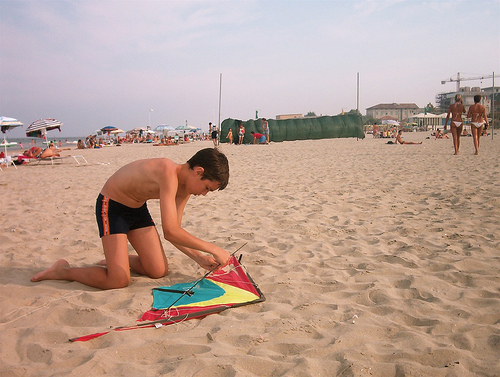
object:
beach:
[0, 145, 500, 377]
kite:
[68, 252, 267, 341]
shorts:
[95, 192, 156, 238]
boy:
[30, 147, 229, 290]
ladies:
[444, 94, 467, 156]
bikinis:
[471, 113, 483, 128]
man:
[394, 130, 423, 144]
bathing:
[393, 130, 423, 145]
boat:
[0, 139, 18, 146]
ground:
[84, 147, 499, 323]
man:
[250, 131, 268, 144]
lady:
[23, 146, 60, 159]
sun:
[81, 72, 155, 102]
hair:
[187, 147, 229, 191]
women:
[467, 94, 489, 155]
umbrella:
[0, 116, 24, 158]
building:
[365, 103, 418, 121]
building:
[435, 86, 499, 116]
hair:
[474, 94, 482, 102]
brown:
[474, 94, 482, 101]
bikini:
[452, 112, 463, 127]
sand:
[263, 176, 481, 279]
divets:
[274, 199, 360, 231]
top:
[255, 290, 266, 304]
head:
[186, 148, 229, 196]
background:
[0, 1, 496, 376]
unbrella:
[25, 118, 63, 148]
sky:
[0, 0, 500, 63]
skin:
[156, 164, 176, 188]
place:
[0, 150, 500, 377]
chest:
[146, 184, 160, 200]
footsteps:
[265, 160, 494, 304]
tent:
[220, 109, 365, 143]